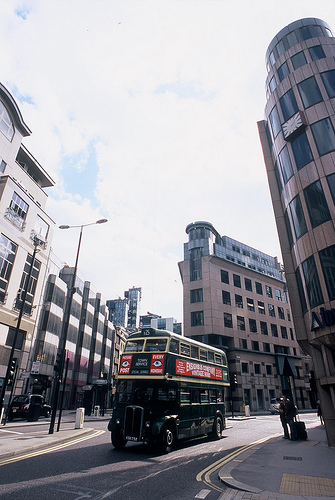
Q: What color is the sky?
A: Blue.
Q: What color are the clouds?
A: White.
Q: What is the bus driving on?
A: The street.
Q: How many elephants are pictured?
A: Zero.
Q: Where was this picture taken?
A: On the street.